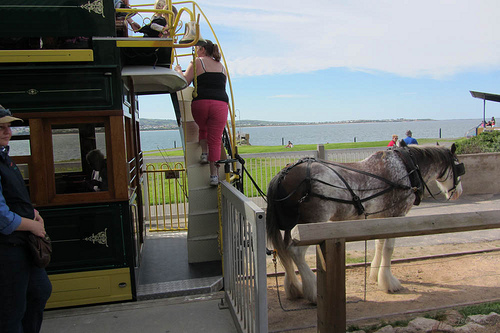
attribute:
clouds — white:
[221, 3, 498, 51]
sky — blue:
[270, 68, 419, 117]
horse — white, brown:
[268, 159, 462, 299]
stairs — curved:
[165, 77, 242, 263]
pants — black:
[7, 246, 74, 330]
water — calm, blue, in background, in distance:
[279, 119, 441, 143]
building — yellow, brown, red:
[2, 11, 183, 301]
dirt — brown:
[424, 253, 492, 306]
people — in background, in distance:
[386, 135, 425, 154]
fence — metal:
[206, 196, 285, 331]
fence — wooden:
[288, 202, 487, 333]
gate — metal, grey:
[214, 180, 278, 327]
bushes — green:
[461, 127, 499, 152]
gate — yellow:
[123, 154, 187, 238]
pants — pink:
[185, 105, 233, 160]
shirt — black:
[200, 62, 228, 109]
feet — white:
[363, 238, 402, 295]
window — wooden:
[26, 110, 127, 198]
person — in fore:
[9, 113, 65, 333]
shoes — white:
[203, 147, 219, 190]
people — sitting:
[63, 2, 174, 63]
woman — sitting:
[128, 1, 175, 46]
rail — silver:
[248, 141, 315, 168]